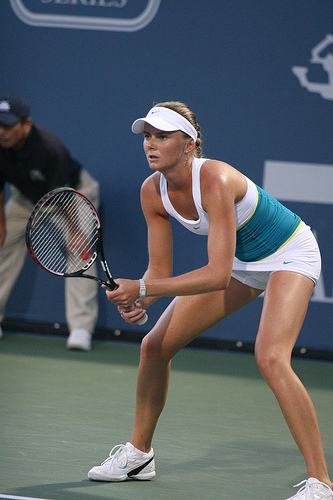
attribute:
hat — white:
[123, 101, 201, 140]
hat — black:
[0, 91, 32, 127]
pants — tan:
[1, 174, 106, 330]